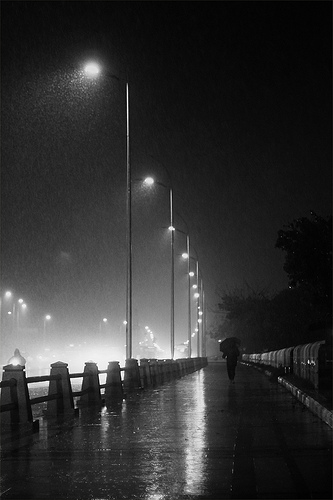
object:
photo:
[1, 1, 332, 499]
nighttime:
[4, 1, 332, 500]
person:
[221, 348, 243, 378]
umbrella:
[220, 334, 253, 357]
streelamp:
[80, 59, 136, 406]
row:
[74, 57, 209, 397]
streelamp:
[142, 173, 178, 370]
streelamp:
[165, 218, 197, 367]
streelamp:
[184, 260, 205, 367]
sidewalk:
[0, 351, 331, 500]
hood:
[223, 342, 242, 360]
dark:
[4, 4, 330, 500]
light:
[137, 360, 210, 499]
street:
[5, 341, 330, 499]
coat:
[220, 349, 243, 378]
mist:
[7, 71, 204, 364]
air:
[4, 6, 330, 377]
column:
[1, 364, 41, 441]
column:
[41, 359, 80, 424]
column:
[78, 363, 104, 410]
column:
[106, 362, 127, 406]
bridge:
[4, 344, 332, 498]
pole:
[20, 373, 54, 410]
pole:
[69, 369, 91, 409]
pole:
[96, 364, 113, 403]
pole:
[122, 360, 132, 390]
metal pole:
[119, 85, 137, 363]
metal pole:
[165, 189, 180, 357]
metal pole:
[186, 236, 197, 363]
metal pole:
[192, 257, 202, 367]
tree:
[281, 210, 332, 346]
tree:
[221, 285, 295, 350]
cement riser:
[227, 337, 330, 387]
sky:
[2, 0, 331, 355]